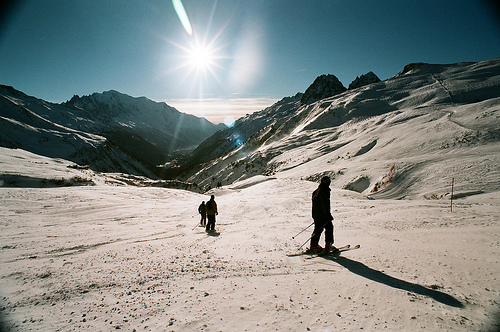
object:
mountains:
[0, 85, 182, 178]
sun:
[175, 33, 217, 83]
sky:
[0, 0, 499, 127]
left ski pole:
[290, 221, 313, 240]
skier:
[308, 175, 338, 256]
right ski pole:
[297, 227, 325, 250]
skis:
[304, 244, 360, 259]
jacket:
[311, 188, 331, 222]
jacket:
[205, 201, 217, 215]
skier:
[205, 195, 222, 233]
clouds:
[166, 97, 276, 128]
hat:
[321, 174, 332, 182]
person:
[198, 200, 207, 226]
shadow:
[326, 251, 462, 310]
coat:
[199, 205, 207, 213]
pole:
[192, 217, 206, 230]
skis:
[199, 221, 207, 228]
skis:
[197, 227, 218, 235]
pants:
[310, 218, 334, 247]